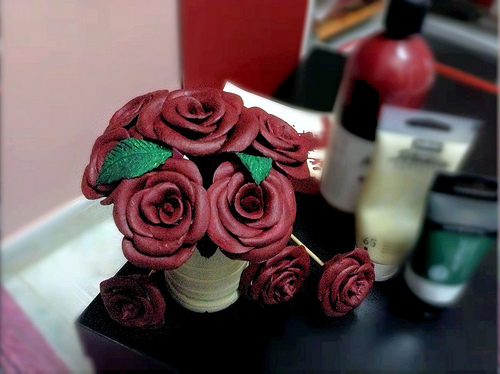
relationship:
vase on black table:
[162, 247, 249, 312] [78, 43, 500, 374]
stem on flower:
[280, 220, 330, 275] [312, 249, 387, 316]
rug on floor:
[2, 193, 137, 372] [1, 195, 170, 370]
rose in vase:
[315, 246, 378, 316] [160, 239, 252, 314]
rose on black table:
[315, 246, 375, 320] [78, 43, 500, 374]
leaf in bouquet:
[94, 133, 176, 188] [74, 78, 315, 267]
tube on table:
[401, 165, 499, 315] [68, 266, 498, 372]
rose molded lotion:
[315, 246, 378, 316] [353, 101, 485, 282]